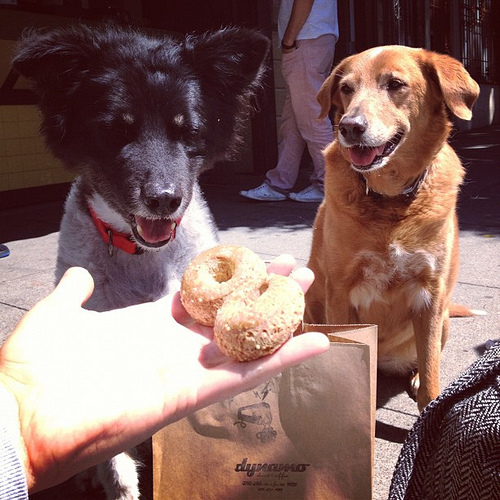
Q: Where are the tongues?
A: On dogs.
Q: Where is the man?
A: Behind dogs.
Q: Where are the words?
A: On bag.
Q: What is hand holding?
A: Food.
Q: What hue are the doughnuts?
A: Tan.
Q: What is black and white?
A: Fabric.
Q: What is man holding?
A: Donuts.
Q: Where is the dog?
A: Sidewalk.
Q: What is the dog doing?
A: Sitting.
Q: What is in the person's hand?
A: Two doughnuts.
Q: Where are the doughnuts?
A: In the person's hand.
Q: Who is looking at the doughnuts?
A: Two dogs.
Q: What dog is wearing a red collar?
A: The one on the left.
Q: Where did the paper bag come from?
A: Dynamo.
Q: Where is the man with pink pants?
A: Walking in the background.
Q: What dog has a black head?
A: The one on the left.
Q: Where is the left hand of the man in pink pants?
A: In his pocket.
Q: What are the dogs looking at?
A: Two doughnuts.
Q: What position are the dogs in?
A: Sitting.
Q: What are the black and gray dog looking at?
A: Donuts.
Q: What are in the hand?
A: Two dog treats.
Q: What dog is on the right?
A: A brown furry dog.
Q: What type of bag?
A: A brown paper bag.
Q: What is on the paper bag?
A: Writing.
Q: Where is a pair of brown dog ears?
A: Brown dog.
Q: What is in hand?
A: Two donuts.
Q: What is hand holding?
A: Two donuts.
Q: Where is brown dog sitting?
A: On ground.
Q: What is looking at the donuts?
A: The brown dog.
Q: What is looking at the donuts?
A: The black dog.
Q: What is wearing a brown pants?
A: The man.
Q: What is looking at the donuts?
A: The dog.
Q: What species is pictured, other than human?
A: Canine.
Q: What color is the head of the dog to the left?
A: Black.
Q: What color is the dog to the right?
A: Tan.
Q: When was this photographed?
A: Daytime.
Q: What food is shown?
A: Doughnuts.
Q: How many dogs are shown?
A: Two.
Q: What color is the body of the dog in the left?
A: White.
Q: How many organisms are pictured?
A: Four.